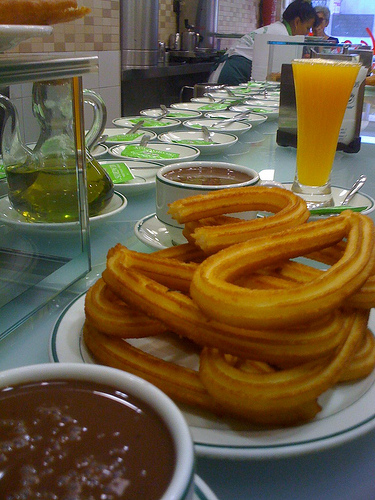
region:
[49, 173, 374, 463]
Chorros on a plate.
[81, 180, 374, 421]
Chorros are stacked high.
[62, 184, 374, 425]
Chorros are golden and crispy.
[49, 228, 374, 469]
Plate is white with green trim.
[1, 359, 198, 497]
Bowl of sauce next to chorros.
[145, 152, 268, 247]
Bowl is white with green trim.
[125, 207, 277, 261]
Bowl is sitting on a saucer.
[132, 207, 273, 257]
Saucer is white with green trim.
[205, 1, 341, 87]
Woman are working in background.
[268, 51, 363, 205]
Glass is filled to the top.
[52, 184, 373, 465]
Stack of chorros on plate.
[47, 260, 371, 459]
The plate is white.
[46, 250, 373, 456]
The plate has green trim.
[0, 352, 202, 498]
Sauce in a bowl.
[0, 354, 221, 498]
Bowl is on a saucer.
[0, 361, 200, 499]
Bowl is next to plate.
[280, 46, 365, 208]
Glass is completely filled.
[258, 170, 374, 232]
Glass is sitting on a saucer.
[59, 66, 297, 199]
The counter is lined with plates.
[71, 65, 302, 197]
All the plates have silverware on them.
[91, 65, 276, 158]
bowls aligned across a table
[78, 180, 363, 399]
loops and curls of fried dough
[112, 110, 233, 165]
green packets and spoons in bowls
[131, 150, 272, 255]
cup of brown soup in bowl and saucer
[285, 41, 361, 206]
yellow beverage in tall and curved container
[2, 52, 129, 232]
glass pitcher of oil in a saucer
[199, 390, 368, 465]
green stripes around edge of plate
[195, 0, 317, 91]
woman wearing apron leaning over at edge of counter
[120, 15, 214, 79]
coffee urn and smaller pots in alcove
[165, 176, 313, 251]
ridged doughnut shaped like a horseshoe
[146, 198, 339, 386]
plate of piled up churros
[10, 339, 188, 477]
bowl of chocolate syrup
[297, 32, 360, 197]
tall glass of orange juice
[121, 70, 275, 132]
row of small dining plates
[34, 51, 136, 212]
glass oil and vinegar pourer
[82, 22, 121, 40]
different shades of brown back splash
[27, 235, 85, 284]
glass case for restaurant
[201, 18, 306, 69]
woman server with green apron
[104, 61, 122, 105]
white restaurant tile on wall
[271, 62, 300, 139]
stainless steel napkin holder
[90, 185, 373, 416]
plate of churros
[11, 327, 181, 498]
bowl of melted chocolate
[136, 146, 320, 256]
cup of hot chocolate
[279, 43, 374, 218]
glass of orange juice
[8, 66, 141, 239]
green tea in jug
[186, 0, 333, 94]
lady wearing green apron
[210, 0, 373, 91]
lady wearing white uniform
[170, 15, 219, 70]
silver teapots on counter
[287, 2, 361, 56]
lady waiting to be served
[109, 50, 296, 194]
side plates with spoons on them